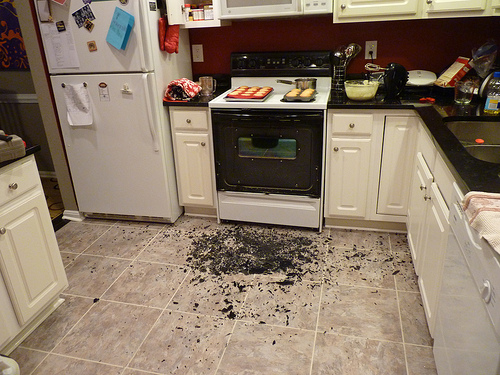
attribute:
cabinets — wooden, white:
[331, 2, 495, 25]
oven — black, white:
[212, 110, 326, 201]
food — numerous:
[227, 81, 320, 101]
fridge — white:
[32, 1, 186, 223]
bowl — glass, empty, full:
[341, 74, 385, 99]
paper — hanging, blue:
[101, 4, 138, 57]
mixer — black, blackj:
[367, 56, 412, 101]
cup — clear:
[450, 80, 479, 110]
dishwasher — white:
[419, 175, 500, 374]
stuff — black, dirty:
[197, 229, 317, 275]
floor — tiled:
[79, 287, 374, 363]